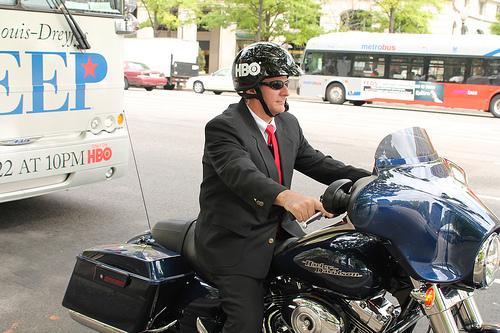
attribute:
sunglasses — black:
[243, 69, 314, 89]